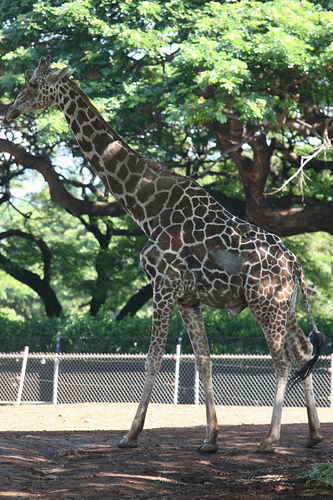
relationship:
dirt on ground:
[0, 404, 332, 497] [1, 402, 322, 498]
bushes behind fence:
[0, 315, 331, 350] [1, 343, 322, 411]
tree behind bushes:
[0, 228, 65, 319] [1, 312, 332, 356]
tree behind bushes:
[66, 153, 161, 315] [1, 312, 332, 356]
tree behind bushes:
[113, 280, 154, 323] [1, 312, 332, 356]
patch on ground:
[291, 453, 329, 486] [1, 402, 322, 498]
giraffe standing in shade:
[6, 53, 324, 454] [1, 415, 323, 498]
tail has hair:
[289, 331, 328, 391] [282, 356, 312, 401]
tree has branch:
[1, 2, 318, 238] [0, 111, 332, 239]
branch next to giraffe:
[0, 111, 332, 239] [6, 53, 324, 454]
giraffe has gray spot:
[6, 53, 324, 454] [204, 236, 244, 273]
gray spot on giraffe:
[204, 236, 244, 273] [6, 53, 324, 454]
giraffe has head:
[6, 53, 324, 454] [2, 51, 80, 134]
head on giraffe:
[2, 51, 80, 134] [6, 53, 324, 454]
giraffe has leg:
[6, 53, 324, 454] [176, 309, 224, 457]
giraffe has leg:
[6, 53, 324, 454] [113, 301, 172, 450]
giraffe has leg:
[6, 53, 324, 454] [250, 309, 295, 454]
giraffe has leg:
[6, 53, 324, 454] [285, 321, 322, 450]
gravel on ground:
[0, 403, 330, 422] [1, 402, 322, 498]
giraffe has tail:
[8, 0, 322, 324] [282, 263, 323, 399]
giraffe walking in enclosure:
[6, 53, 324, 454] [0, 352, 329, 406]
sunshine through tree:
[8, 165, 97, 222] [1, 2, 318, 238]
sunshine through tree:
[8, 165, 97, 222] [1, 225, 66, 316]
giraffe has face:
[6, 53, 324, 454] [4, 67, 54, 125]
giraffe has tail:
[6, 53, 324, 454] [284, 249, 322, 395]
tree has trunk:
[1, 217, 82, 330] [4, 275, 79, 322]